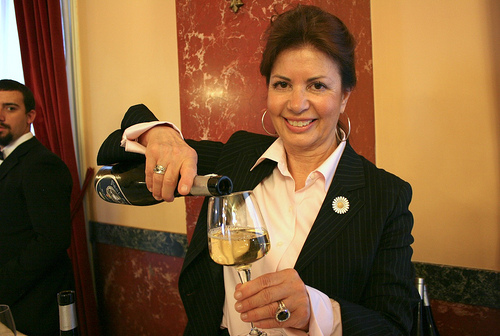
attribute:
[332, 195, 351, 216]
daisy — white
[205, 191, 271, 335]
glass — partially filled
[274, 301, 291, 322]
ring — gold, black, silver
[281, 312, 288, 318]
stone — blue, black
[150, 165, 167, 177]
bands — silver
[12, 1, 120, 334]
curtain — red, pleated, tied back, scarlet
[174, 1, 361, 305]
marble — red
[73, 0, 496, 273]
wall — cream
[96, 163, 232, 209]
bottle — black, opened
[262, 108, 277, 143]
earing — silver, hoop, large, gold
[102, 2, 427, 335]
woman — pouring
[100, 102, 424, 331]
jacket — black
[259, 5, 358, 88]
hair — brown, black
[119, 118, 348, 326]
shirt — white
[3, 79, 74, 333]
man — standing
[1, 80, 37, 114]
hair — short